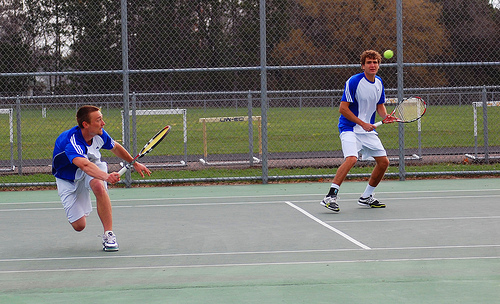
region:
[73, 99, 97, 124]
The man has a low cut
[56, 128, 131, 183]
The man is wearing a blue shirt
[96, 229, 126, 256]
Only one sneaker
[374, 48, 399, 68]
The tennis ball is in the air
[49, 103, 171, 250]
man holding a tennis racket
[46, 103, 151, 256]
man running on a tennis court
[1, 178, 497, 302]
green and gray tennis court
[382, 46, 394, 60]
bright yellow green tennis ball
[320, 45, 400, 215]
man wearing white shorts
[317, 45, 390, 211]
man wearing ankle brace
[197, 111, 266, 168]
wood track hurdle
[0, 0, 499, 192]
metal chain link silver fence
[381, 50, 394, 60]
TENNIS BALL IN THE AIR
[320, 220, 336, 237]
WHITE LINE ON THE COURT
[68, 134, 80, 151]
WHITE STRIPES ONTHE SLEEVES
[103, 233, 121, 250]
MAN HAS ON TENNIS SHOES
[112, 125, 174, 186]
MAN HOLDING A TENNIS RAQUET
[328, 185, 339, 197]
BLACK ANKLE BAND AROUND LEG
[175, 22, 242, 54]
FENCE GOING AROUND THE COURT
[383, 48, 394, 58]
Yellow tennis ball in the air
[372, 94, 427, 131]
Tennis racket in man's hand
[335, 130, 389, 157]
White shirt on a man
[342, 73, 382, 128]
Blue and white shirt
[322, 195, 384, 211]
Two shoes on a man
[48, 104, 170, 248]
Tennis player lunging for the ball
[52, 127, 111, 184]
Blue shirt on a man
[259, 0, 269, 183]
Tall metal pole near a tennis court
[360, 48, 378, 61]
Brown hair on a man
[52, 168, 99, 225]
White shorts on a man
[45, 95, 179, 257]
a man in white and blue with a tennis racket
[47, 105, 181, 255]
a guy playing tennis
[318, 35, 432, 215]
a young man plays tennis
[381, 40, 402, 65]
a tennis ball flying through air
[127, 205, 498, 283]
a green tennis court surface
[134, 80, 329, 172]
a track field behind a fence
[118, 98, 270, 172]
hurdles on a track field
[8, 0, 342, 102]
dark forests outside a fence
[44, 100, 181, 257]
a boy with short hair plays sports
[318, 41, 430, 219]
a guy gets ready to hit tennis ball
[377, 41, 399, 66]
A tennis ball in the air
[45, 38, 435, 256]
Two men are playing tennis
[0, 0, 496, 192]
A fence behind the tennis players